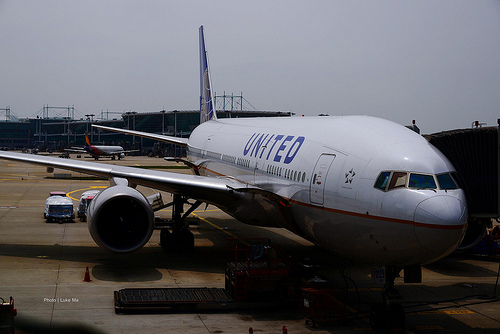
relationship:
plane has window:
[1, 22, 498, 332] [372, 170, 392, 192]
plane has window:
[1, 22, 498, 332] [387, 169, 409, 189]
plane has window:
[1, 22, 498, 332] [408, 171, 439, 189]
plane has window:
[1, 22, 498, 332] [434, 172, 459, 189]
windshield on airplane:
[369, 166, 472, 198] [56, 130, 135, 166]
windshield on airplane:
[369, 166, 472, 198] [1, 19, 496, 309]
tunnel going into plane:
[420, 128, 499, 219] [1, 22, 498, 332]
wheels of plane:
[380, 285, 401, 319] [5, 24, 495, 283]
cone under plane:
[82, 265, 93, 283] [1, 22, 498, 332]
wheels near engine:
[159, 218, 199, 263] [85, 183, 155, 255]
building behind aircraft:
[1, 103, 493, 228] [1, 24, 470, 289]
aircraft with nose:
[73, 20, 478, 256] [412, 193, 470, 254]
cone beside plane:
[80, 264, 93, 284] [1, 22, 498, 332]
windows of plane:
[186, 144, 308, 182] [0, 24, 469, 269]